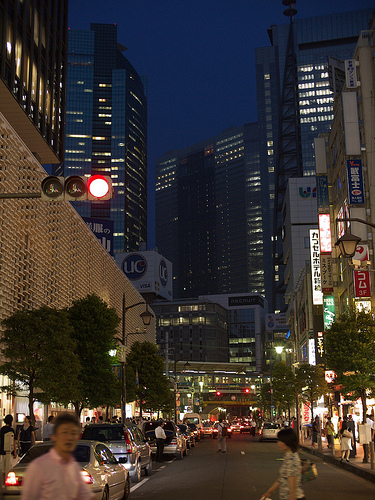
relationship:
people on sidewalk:
[302, 407, 361, 455] [290, 425, 373, 480]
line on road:
[129, 473, 150, 492] [65, 411, 375, 500]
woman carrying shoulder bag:
[260, 426, 305, 500] [297, 460, 318, 484]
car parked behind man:
[6, 440, 130, 498] [22, 415, 98, 497]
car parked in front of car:
[86, 420, 154, 481] [6, 440, 130, 498]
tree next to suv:
[6, 304, 80, 447] [73, 417, 157, 481]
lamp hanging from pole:
[138, 311, 154, 326] [121, 293, 144, 444]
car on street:
[86, 420, 154, 481] [51, 419, 360, 495]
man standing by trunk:
[152, 417, 165, 464] [141, 418, 179, 447]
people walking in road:
[193, 412, 301, 450] [65, 411, 363, 496]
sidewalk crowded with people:
[281, 429, 362, 480] [307, 416, 361, 456]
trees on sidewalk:
[0, 291, 119, 426] [5, 419, 149, 476]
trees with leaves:
[0, 291, 119, 426] [5, 297, 109, 403]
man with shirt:
[22, 415, 98, 497] [21, 453, 91, 498]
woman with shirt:
[260, 426, 305, 497] [277, 454, 302, 499]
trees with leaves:
[11, 306, 123, 423] [6, 297, 117, 399]